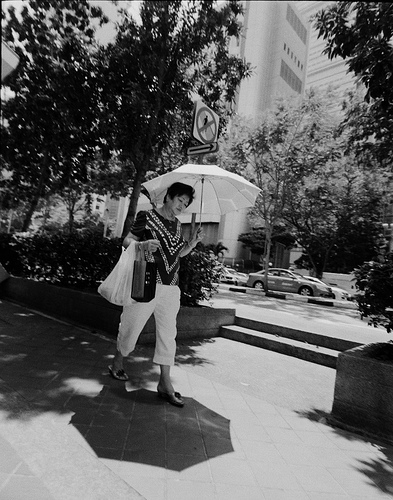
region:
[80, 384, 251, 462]
shadow of large umbrella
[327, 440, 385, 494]
shadow of trees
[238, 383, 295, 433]
lines on asphalt ground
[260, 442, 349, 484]
white asphalt ground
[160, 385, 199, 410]
woman's shoes with flower design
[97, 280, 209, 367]
woman wearing white cargo pants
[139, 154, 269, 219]
woman holding white open umbrella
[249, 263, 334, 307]
car parked in parking lot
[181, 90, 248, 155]
sign with white circle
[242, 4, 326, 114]
large white building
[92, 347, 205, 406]
The woman is wearing sandals.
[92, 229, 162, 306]
The woman is carrying bags on her forearm.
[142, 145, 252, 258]
The woman is holding an umbrella with her left hand.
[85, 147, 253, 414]
A woman is using an umbrella to shield herself from the sun.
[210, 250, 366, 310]
Traffic.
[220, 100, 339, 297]
A tree on the edge of the sidewalk.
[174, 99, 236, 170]
Two street signs.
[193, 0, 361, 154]
A multistory building.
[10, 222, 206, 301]
A small hedge.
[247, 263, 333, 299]
A car.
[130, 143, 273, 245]
The woman is holding an umbrella.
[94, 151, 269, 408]
The woman is walking on the street.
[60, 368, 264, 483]
The umbrella's shadow is on the ground.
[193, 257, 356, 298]
Cars are parked on the street.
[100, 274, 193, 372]
The woman wears white pants.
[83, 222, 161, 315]
The woman is carrying two bags.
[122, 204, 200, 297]
The woman wears a graphic top.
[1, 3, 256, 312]
Trees line the street.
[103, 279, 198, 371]
The woman's pants are cropped.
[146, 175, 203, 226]
The woman is looking down at the ground.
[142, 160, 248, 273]
Umbrella prepared for inclement weather.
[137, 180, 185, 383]
Summer white Capri pants.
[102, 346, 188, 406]
Thong sandals both feet.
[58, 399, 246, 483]
Umbrella shadow on pavement.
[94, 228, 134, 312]
Plastic bag right arm.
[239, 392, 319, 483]
Walkway concrete paving shown.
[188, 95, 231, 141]
No walk sign overhead.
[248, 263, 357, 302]
Two cars street traffic.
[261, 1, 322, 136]
Tall skyscraper windows building.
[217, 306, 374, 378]
Concrete steps in walkway.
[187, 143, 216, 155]
Arrow sign above woman.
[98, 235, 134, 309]
White plastic bag hanging from woman's arm.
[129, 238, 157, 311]
Black bag hanging from woman's wrist.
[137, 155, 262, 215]
White umbrella being held by woman.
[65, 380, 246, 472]
Shadow of umbrella on the ground.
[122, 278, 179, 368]
White capri shorts worn by the woman.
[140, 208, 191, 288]
Black and white designed shirt worn by woman.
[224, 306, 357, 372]
Two steps leading to the sidewalk.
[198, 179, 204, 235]
Umbrella post held by woman.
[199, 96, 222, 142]
White sign above arrow sign.